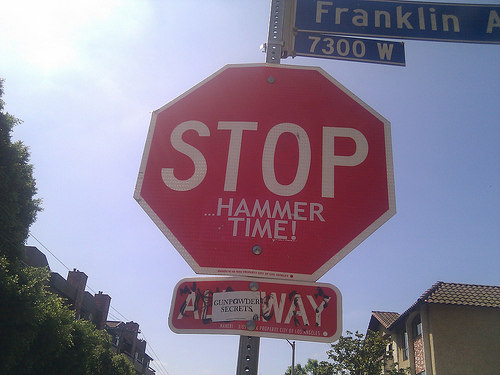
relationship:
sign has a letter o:
[129, 61, 399, 278] [266, 113, 318, 204]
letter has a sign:
[320, 124, 370, 201] [129, 61, 399, 278]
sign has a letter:
[129, 61, 399, 278] [210, 197, 234, 219]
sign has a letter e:
[129, 61, 399, 278] [293, 200, 308, 220]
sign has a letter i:
[129, 61, 399, 278] [243, 218, 248, 240]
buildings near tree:
[361, 280, 498, 373] [279, 322, 398, 372]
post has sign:
[233, 336, 263, 373] [129, 61, 399, 278]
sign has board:
[129, 61, 399, 278] [169, 39, 386, 291]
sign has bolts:
[129, 61, 399, 278] [253, 70, 286, 260]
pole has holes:
[242, 325, 263, 371] [238, 340, 255, 373]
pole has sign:
[237, 0, 292, 375] [129, 61, 399, 278]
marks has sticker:
[164, 276, 344, 345] [210, 288, 266, 325]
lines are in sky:
[27, 232, 152, 338] [3, 1, 495, 373]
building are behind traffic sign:
[18, 246, 159, 375] [130, 48, 403, 342]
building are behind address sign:
[18, 246, 159, 375] [262, 4, 486, 66]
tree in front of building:
[0, 77, 45, 259] [51, 259, 86, 314]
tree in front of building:
[0, 76, 145, 375] [18, 246, 159, 375]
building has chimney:
[51, 259, 86, 314] [70, 262, 87, 284]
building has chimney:
[18, 246, 159, 375] [94, 291, 112, 328]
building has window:
[51, 259, 86, 314] [77, 307, 87, 321]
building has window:
[18, 246, 159, 375] [58, 292, 75, 309]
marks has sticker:
[164, 276, 344, 345] [205, 285, 272, 330]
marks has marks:
[164, 276, 344, 345] [182, 270, 333, 330]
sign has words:
[129, 61, 399, 278] [202, 198, 324, 239]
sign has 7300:
[88, 48, 410, 276] [308, 35, 366, 57]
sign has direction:
[88, 48, 410, 276] [372, 27, 395, 72]